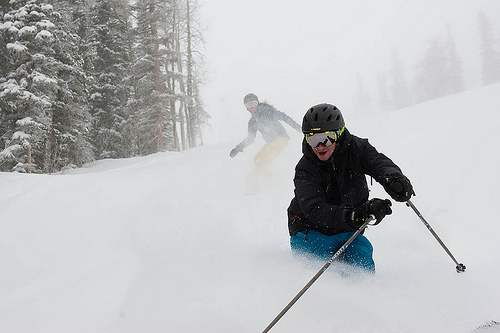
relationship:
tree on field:
[174, 0, 203, 157] [0, 88, 480, 329]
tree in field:
[345, 61, 378, 112] [0, 88, 480, 329]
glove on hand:
[355, 197, 390, 229] [347, 199, 391, 221]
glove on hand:
[385, 172, 412, 204] [385, 172, 412, 202]